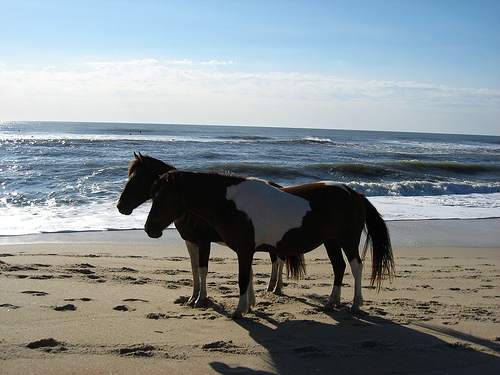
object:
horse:
[144, 169, 397, 320]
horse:
[117, 151, 307, 304]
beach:
[0, 244, 499, 372]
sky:
[0, 0, 499, 134]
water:
[0, 119, 499, 233]